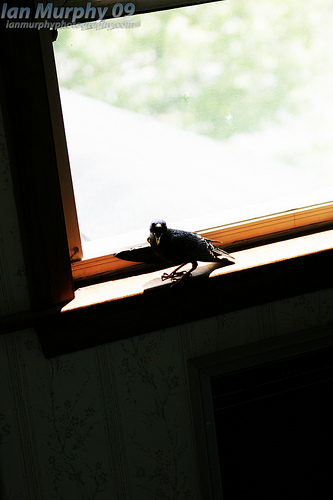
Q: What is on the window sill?
A: Bird.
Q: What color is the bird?
A: Black.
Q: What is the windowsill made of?
A: Wood.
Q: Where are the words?
A: Top left side.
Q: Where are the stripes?
A: On the wall.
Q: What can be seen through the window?
A: The outdoors.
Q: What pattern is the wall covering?
A: Floral.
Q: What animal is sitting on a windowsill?
A: Bird.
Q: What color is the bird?
A: Black.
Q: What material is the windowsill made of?
A: Wood.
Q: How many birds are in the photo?
A: One.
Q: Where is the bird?
A: On a windowsill.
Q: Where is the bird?
A: On the window.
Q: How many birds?
A: One.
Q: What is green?
A: The tree.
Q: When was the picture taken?
A: Daytime.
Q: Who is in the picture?
A: Bird.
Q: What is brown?
A: The window.